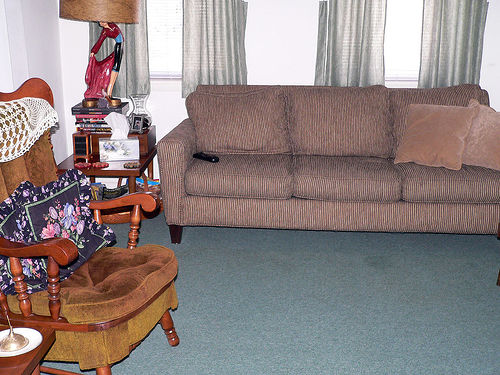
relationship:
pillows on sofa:
[393, 101, 472, 175] [157, 84, 499, 244]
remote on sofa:
[191, 149, 219, 168] [157, 84, 499, 244]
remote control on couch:
[191, 149, 219, 168] [157, 84, 499, 244]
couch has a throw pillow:
[157, 84, 499, 244] [393, 101, 472, 175]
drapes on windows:
[180, 0, 246, 99] [245, 0, 316, 85]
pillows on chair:
[1, 171, 114, 291] [1, 77, 179, 374]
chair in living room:
[1, 77, 179, 374] [0, 2, 499, 373]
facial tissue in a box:
[105, 112, 133, 139] [98, 137, 140, 163]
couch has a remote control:
[157, 84, 499, 244] [191, 149, 219, 168]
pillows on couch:
[393, 101, 472, 175] [157, 84, 499, 244]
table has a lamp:
[57, 149, 155, 199] [58, 1, 139, 114]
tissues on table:
[98, 110, 140, 164] [57, 149, 155, 199]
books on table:
[73, 112, 112, 134] [57, 149, 155, 199]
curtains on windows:
[315, 2, 387, 87] [245, 0, 316, 85]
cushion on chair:
[59, 246, 179, 325] [1, 77, 179, 374]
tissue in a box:
[105, 112, 133, 139] [98, 137, 140, 163]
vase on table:
[127, 93, 153, 129] [57, 149, 155, 199]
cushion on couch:
[292, 155, 400, 200] [157, 84, 499, 244]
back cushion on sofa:
[185, 91, 290, 157] [157, 84, 499, 244]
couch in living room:
[157, 84, 499, 244] [0, 2, 499, 373]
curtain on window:
[315, 2, 387, 87] [245, 0, 316, 85]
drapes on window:
[180, 0, 246, 99] [245, 0, 316, 85]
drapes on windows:
[138, 1, 488, 89] [245, 0, 316, 85]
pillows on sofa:
[393, 104, 476, 171] [157, 84, 499, 244]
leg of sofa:
[169, 224, 186, 246] [157, 84, 499, 244]